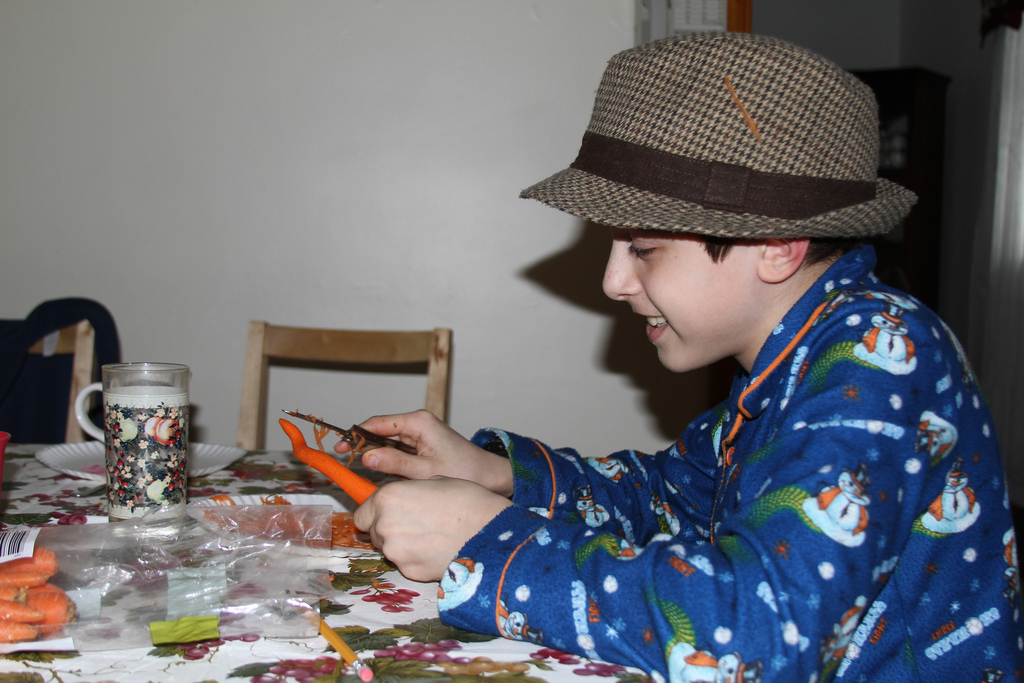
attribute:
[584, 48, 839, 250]
hat — brown, black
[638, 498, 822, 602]
pajamas — blue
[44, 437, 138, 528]
plate — paper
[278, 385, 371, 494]
carrot — orange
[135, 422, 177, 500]
design — floral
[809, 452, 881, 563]
snow man — cartoon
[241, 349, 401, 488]
device — for cutting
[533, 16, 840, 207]
hat — brown, plaid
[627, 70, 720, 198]
accents — brown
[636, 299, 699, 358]
smile — toothy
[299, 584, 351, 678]
pencil — yellow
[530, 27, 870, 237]
hat — checkered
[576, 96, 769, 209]
band — solid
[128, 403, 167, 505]
designs — Christmas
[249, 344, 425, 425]
chair — wooden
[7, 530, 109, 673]
bag — plastic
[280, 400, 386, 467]
vegetable peeler — metal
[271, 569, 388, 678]
pencil — yellow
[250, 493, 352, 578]
peeling — carrot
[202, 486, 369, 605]
plate — paper